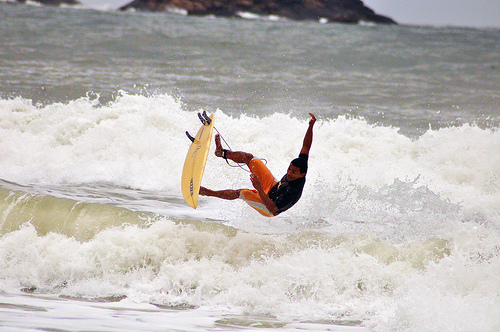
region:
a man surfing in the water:
[174, 98, 331, 238]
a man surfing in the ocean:
[167, 74, 331, 229]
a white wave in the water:
[346, 114, 494, 286]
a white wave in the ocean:
[367, 106, 471, 269]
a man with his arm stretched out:
[274, 90, 328, 191]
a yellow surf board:
[178, 90, 235, 211]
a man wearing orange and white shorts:
[242, 140, 282, 237]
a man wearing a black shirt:
[248, 145, 311, 223]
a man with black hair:
[273, 156, 308, 184]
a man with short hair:
[277, 153, 317, 184]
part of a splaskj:
[390, 188, 421, 227]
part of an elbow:
[267, 195, 287, 245]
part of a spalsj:
[360, 183, 390, 222]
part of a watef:
[358, 148, 386, 213]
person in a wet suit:
[172, 88, 320, 221]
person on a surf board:
[172, 88, 324, 228]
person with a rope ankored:
[147, 90, 332, 222]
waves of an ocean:
[25, 69, 459, 246]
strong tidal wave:
[57, 103, 492, 257]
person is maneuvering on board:
[159, 83, 341, 235]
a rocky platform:
[70, 2, 407, 26]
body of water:
[109, 19, 406, 87]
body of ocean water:
[190, 38, 422, 113]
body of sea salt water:
[187, 24, 444, 101]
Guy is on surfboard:
[172, 85, 317, 232]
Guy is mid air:
[177, 83, 321, 239]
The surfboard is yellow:
[175, 100, 232, 219]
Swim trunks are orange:
[235, 136, 281, 230]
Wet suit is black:
[262, 138, 313, 223]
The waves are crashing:
[0, 75, 493, 324]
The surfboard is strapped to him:
[193, 99, 266, 175]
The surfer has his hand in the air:
[165, 69, 322, 227]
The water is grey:
[0, 0, 496, 153]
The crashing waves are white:
[7, 219, 497, 330]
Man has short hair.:
[283, 155, 314, 180]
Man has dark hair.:
[290, 148, 317, 180]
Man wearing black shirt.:
[278, 180, 320, 227]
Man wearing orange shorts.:
[247, 159, 289, 216]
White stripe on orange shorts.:
[246, 198, 280, 228]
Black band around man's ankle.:
[214, 145, 243, 170]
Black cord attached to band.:
[206, 111, 241, 170]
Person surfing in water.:
[175, 103, 237, 230]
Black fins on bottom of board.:
[173, 105, 224, 148]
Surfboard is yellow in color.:
[166, 123, 242, 224]